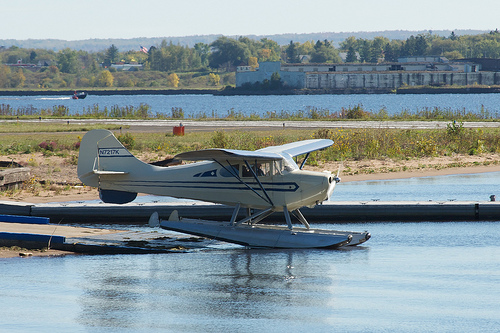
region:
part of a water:
[243, 242, 288, 321]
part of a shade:
[278, 277, 309, 307]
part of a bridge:
[349, 170, 419, 245]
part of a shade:
[259, 275, 304, 320]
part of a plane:
[316, 206, 360, 242]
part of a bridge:
[364, 180, 414, 228]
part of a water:
[351, 288, 389, 330]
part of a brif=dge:
[378, 191, 421, 251]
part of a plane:
[126, 188, 193, 283]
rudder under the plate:
[188, 218, 371, 254]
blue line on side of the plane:
[223, 175, 310, 196]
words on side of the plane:
[86, 142, 136, 161]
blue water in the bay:
[72, 272, 297, 305]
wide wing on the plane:
[180, 137, 276, 169]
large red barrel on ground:
[155, 117, 199, 137]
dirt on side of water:
[358, 158, 428, 171]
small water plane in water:
[53, 110, 377, 245]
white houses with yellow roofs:
[311, 54, 448, 94]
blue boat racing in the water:
[59, 83, 96, 101]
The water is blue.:
[0, 91, 499, 331]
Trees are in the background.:
[1, 36, 499, 92]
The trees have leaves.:
[0, 29, 498, 88]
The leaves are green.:
[1, 30, 498, 83]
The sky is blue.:
[1, 0, 499, 39]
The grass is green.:
[1, 103, 498, 202]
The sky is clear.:
[0, 0, 499, 40]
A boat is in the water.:
[71, 88, 87, 98]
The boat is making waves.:
[36, 89, 86, 101]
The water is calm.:
[0, 94, 499, 331]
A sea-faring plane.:
[66, 113, 371, 262]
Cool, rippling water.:
[387, 232, 482, 316]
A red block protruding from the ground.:
[166, 121, 188, 138]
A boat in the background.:
[72, 87, 89, 99]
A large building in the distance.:
[224, 54, 496, 88]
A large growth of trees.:
[146, 40, 203, 68]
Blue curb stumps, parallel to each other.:
[0, 209, 67, 244]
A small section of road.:
[193, 116, 274, 131]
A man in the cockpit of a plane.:
[243, 160, 265, 177]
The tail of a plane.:
[69, 120, 148, 205]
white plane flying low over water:
[67, 115, 384, 260]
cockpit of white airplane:
[217, 156, 303, 186]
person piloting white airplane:
[247, 162, 266, 178]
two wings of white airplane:
[174, 128, 346, 168]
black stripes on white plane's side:
[114, 175, 301, 191]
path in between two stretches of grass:
[2, 110, 498, 135]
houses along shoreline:
[234, 56, 499, 87]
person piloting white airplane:
[240, 158, 283, 182]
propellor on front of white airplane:
[327, 158, 352, 199]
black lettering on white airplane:
[92, 142, 133, 164]